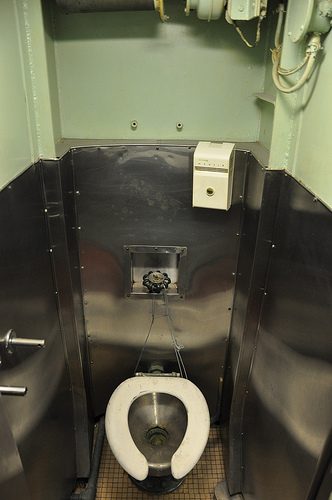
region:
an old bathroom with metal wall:
[7, 8, 330, 499]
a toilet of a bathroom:
[99, 361, 214, 487]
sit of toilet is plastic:
[99, 370, 216, 484]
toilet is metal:
[101, 371, 214, 496]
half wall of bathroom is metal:
[0, 148, 331, 498]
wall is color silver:
[3, 144, 330, 498]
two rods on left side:
[2, 321, 49, 406]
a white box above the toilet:
[183, 136, 243, 216]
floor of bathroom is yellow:
[88, 415, 228, 499]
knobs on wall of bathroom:
[36, 184, 96, 362]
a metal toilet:
[101, 355, 225, 499]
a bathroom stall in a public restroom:
[23, 166, 318, 487]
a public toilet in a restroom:
[95, 332, 223, 487]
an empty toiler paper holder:
[21, 328, 53, 402]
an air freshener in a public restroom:
[178, 138, 277, 225]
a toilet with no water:
[102, 370, 211, 485]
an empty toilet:
[91, 370, 224, 493]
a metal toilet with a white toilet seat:
[95, 364, 220, 486]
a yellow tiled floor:
[102, 468, 133, 498]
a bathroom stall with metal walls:
[40, 159, 256, 499]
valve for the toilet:
[141, 265, 171, 295]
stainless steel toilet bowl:
[98, 359, 215, 498]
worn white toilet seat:
[102, 366, 212, 482]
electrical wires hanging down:
[215, 3, 328, 97]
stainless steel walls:
[1, 132, 329, 499]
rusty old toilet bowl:
[99, 370, 217, 497]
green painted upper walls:
[1, 1, 329, 213]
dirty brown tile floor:
[95, 408, 227, 499]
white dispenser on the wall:
[188, 137, 240, 218]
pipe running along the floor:
[65, 398, 115, 499]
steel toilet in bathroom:
[106, 370, 203, 483]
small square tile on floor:
[196, 493, 200, 497]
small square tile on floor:
[204, 482, 208, 487]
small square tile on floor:
[203, 474, 208, 478]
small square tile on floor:
[204, 465, 208, 470]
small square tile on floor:
[114, 487, 120, 493]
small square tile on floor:
[110, 483, 116, 489]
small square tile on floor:
[99, 491, 104, 496]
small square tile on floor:
[106, 477, 112, 482]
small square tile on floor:
[106, 469, 111, 473]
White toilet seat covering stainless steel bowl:
[102, 375, 212, 490]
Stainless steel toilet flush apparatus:
[0, 329, 47, 354]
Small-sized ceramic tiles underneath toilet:
[98, 478, 126, 496]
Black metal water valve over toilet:
[140, 268, 171, 293]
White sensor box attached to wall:
[188, 140, 238, 212]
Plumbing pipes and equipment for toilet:
[272, 3, 330, 93]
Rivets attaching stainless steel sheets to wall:
[70, 188, 86, 274]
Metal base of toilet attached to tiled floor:
[150, 480, 169, 490]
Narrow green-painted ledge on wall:
[252, 89, 273, 104]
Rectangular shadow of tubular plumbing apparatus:
[51, 13, 161, 37]